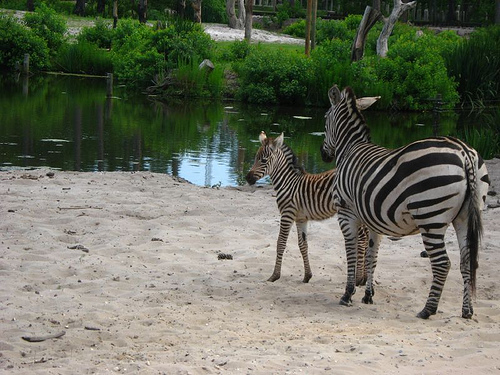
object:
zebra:
[319, 82, 490, 322]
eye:
[321, 115, 330, 124]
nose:
[318, 146, 329, 159]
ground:
[3, 173, 499, 373]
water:
[4, 67, 499, 186]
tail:
[463, 152, 483, 298]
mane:
[340, 87, 374, 150]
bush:
[111, 16, 179, 89]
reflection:
[177, 124, 252, 193]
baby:
[241, 125, 380, 290]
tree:
[215, 2, 257, 30]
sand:
[206, 23, 251, 44]